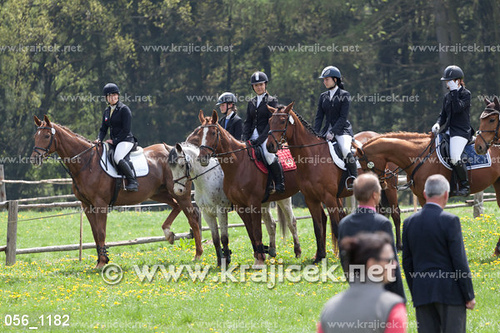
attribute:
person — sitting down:
[99, 69, 154, 207]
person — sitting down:
[207, 81, 253, 147]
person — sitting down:
[242, 63, 289, 201]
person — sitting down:
[305, 65, 365, 185]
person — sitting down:
[439, 49, 480, 223]